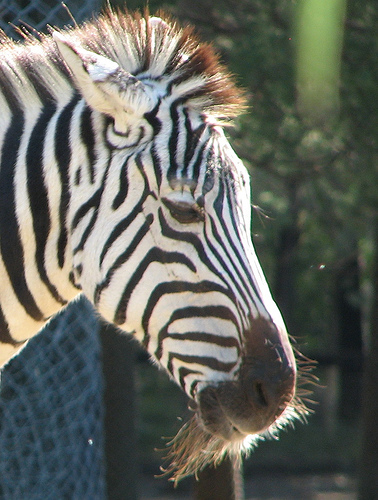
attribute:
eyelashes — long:
[243, 200, 278, 239]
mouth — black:
[193, 386, 252, 445]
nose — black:
[248, 373, 291, 420]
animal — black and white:
[3, 10, 302, 456]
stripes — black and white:
[140, 291, 209, 340]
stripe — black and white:
[89, 148, 177, 275]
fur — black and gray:
[3, 138, 126, 280]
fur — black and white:
[1, 55, 301, 435]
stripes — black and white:
[112, 225, 166, 293]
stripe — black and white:
[149, 297, 200, 359]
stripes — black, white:
[7, 133, 113, 222]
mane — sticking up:
[12, 6, 243, 122]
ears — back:
[41, 37, 146, 110]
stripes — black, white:
[0, 117, 112, 246]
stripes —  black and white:
[2, 12, 317, 478]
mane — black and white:
[0, 0, 252, 129]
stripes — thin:
[113, 223, 275, 462]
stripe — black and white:
[91, 211, 153, 313]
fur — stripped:
[0, 8, 320, 485]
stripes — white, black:
[6, 88, 255, 381]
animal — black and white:
[1, 4, 322, 485]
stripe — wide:
[0, 61, 50, 322]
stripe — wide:
[17, 55, 67, 306]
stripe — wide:
[0, 304, 28, 347]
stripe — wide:
[80, 106, 96, 183]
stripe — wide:
[74, 167, 81, 184]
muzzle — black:
[195, 315, 301, 442]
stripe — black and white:
[140, 280, 245, 346]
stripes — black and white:
[180, 253, 256, 319]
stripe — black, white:
[45, 104, 79, 263]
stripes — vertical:
[113, 144, 259, 317]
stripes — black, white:
[199, 253, 258, 292]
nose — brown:
[228, 350, 300, 436]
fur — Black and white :
[3, 10, 301, 453]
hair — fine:
[144, 379, 315, 485]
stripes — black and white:
[215, 263, 274, 320]